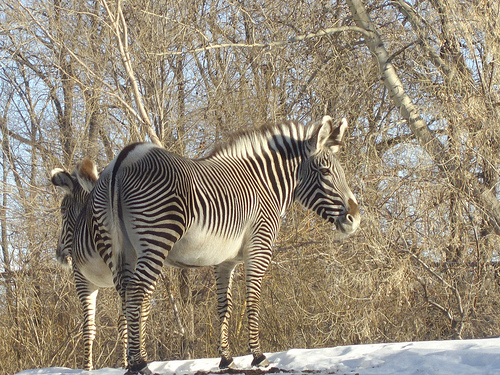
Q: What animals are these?
A: Zebras.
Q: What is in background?
A: Trees.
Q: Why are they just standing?
A: Resting.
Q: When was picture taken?
A: During daylight.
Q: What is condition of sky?
A: Clear.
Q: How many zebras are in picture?
A: Two.